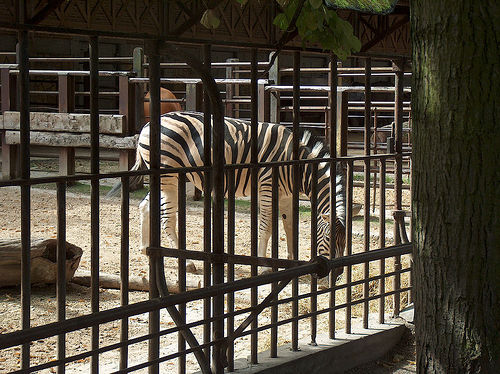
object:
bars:
[0, 0, 419, 374]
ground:
[393, 115, 428, 169]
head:
[313, 205, 363, 280]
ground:
[426, 168, 461, 203]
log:
[410, 0, 499, 374]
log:
[70, 273, 202, 293]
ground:
[1, 148, 408, 370]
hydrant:
[111, 110, 367, 282]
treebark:
[412, 184, 498, 235]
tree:
[402, 5, 498, 372]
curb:
[301, 325, 398, 371]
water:
[30, 35, 136, 322]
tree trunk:
[410, 240, 496, 372]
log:
[1, 236, 82, 289]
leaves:
[272, 12, 362, 61]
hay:
[289, 231, 430, 321]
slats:
[0, 109, 145, 150]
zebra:
[103, 111, 362, 284]